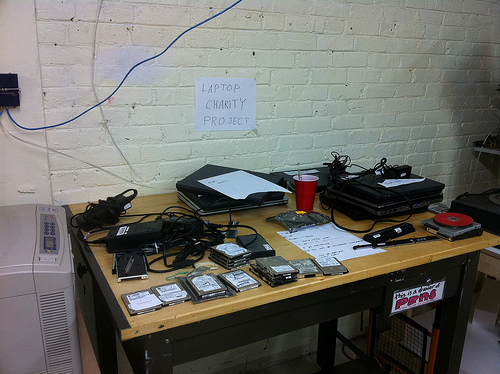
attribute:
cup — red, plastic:
[278, 161, 355, 215]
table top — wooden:
[66, 185, 496, 328]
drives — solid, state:
[113, 231, 350, 315]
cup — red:
[279, 153, 332, 217]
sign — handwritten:
[196, 76, 257, 130]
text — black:
[179, 68, 281, 153]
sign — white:
[186, 63, 281, 145]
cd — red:
[218, 155, 299, 208]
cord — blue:
[2, 2, 243, 129]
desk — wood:
[62, 162, 498, 372]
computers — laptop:
[161, 151, 449, 227]